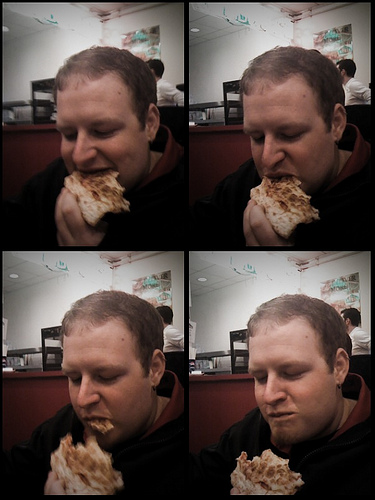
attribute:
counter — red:
[1, 102, 373, 252]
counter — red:
[2, 364, 373, 498]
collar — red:
[145, 367, 187, 426]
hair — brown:
[57, 42, 134, 85]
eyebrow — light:
[61, 368, 80, 375]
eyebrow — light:
[92, 362, 125, 373]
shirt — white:
[154, 81, 182, 104]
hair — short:
[52, 46, 157, 130]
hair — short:
[241, 45, 344, 132]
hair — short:
[62, 289, 163, 376]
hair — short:
[247, 294, 352, 372]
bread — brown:
[229, 449, 303, 494]